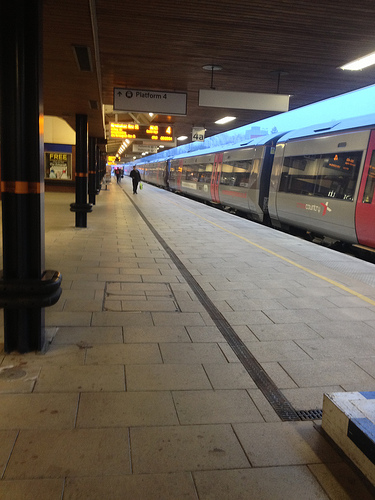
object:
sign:
[113, 86, 188, 117]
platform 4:
[136, 90, 168, 100]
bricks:
[120, 267, 160, 274]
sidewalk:
[4, 147, 373, 499]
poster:
[44, 151, 73, 180]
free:
[49, 153, 68, 161]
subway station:
[2, 3, 372, 500]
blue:
[44, 144, 71, 152]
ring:
[0, 179, 48, 198]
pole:
[3, 2, 64, 359]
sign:
[109, 121, 176, 143]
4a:
[192, 129, 205, 141]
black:
[196, 136, 197, 140]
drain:
[295, 409, 322, 422]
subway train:
[121, 115, 375, 249]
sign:
[198, 89, 292, 114]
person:
[130, 165, 142, 195]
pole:
[68, 113, 93, 227]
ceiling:
[44, 4, 374, 159]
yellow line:
[151, 186, 375, 306]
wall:
[42, 116, 82, 193]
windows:
[220, 162, 260, 190]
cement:
[247, 320, 323, 341]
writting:
[117, 89, 167, 100]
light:
[337, 49, 373, 73]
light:
[214, 115, 236, 125]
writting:
[146, 129, 158, 134]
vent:
[74, 39, 92, 73]